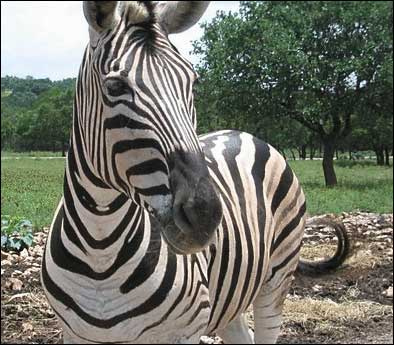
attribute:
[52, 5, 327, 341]
zebra — lone, white, black, animal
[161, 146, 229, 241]
nose — black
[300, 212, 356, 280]
tail — curved, curly, zebra, curling, black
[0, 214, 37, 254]
plant — green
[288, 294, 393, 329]
patches — dry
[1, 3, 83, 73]
sky — clear, grey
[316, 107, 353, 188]
trunk — dark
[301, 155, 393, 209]
grass — green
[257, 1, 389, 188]
plant — green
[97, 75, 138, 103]
eye — zebra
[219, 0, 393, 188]
tree — field, green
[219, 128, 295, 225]
strip — black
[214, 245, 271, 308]
strip — black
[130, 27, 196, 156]
strip — black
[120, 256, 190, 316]
strip — black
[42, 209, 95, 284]
strip — black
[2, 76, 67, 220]
field — overgrown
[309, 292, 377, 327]
grass — dead